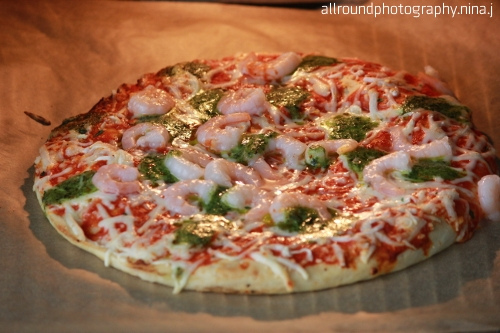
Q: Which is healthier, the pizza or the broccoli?
A: The broccoli is healthier than the pizza.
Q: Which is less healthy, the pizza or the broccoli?
A: The pizza is less healthy than the broccoli.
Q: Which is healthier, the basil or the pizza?
A: The basil is healthier than the pizza.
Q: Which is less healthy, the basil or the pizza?
A: The pizza is less healthy than the basil.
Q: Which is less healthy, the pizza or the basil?
A: The pizza is less healthy than the basil.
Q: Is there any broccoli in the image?
A: Yes, there is broccoli.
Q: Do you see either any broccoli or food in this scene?
A: Yes, there is broccoli.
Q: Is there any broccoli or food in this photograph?
A: Yes, there is broccoli.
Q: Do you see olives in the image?
A: No, there are no olives.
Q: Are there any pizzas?
A: Yes, there is a pizza.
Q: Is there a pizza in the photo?
A: Yes, there is a pizza.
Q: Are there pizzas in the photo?
A: Yes, there is a pizza.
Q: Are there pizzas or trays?
A: Yes, there is a pizza.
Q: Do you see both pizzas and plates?
A: No, there is a pizza but no plates.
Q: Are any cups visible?
A: No, there are no cups.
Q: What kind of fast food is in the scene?
A: The fast food is a pizza.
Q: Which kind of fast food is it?
A: The food is a pizza.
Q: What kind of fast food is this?
A: This is a pizza.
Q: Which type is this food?
A: This is a pizza.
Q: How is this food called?
A: This is a pizza.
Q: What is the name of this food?
A: This is a pizza.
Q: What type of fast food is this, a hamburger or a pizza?
A: This is a pizza.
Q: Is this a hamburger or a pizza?
A: This is a pizza.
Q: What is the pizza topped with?
A: The pizza is topped with broccoli.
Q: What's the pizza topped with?
A: The pizza is topped with broccoli.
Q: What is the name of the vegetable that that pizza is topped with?
A: The vegetable is broccoli.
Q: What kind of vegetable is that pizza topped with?
A: The pizza is topped with broccoli.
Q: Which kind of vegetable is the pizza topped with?
A: The pizza is topped with broccoli.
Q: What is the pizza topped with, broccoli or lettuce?
A: The pizza is topped with broccoli.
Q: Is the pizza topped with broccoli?
A: Yes, the pizza is topped with broccoli.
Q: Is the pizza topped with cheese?
A: No, the pizza is topped with broccoli.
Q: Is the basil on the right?
A: Yes, the basil is on the right of the image.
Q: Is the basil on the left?
A: No, the basil is on the right of the image.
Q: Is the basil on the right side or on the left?
A: The basil is on the right of the image.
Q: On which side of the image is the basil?
A: The basil is on the right of the image.